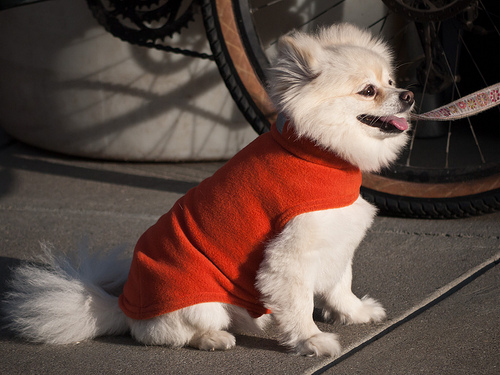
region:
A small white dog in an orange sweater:
[6, 23, 416, 360]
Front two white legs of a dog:
[256, 205, 384, 357]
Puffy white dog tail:
[6, 240, 132, 345]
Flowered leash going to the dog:
[398, 83, 498, 123]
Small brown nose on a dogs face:
[396, 85, 415, 106]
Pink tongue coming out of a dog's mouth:
[378, 113, 408, 132]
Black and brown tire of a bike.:
[199, 1, 497, 217]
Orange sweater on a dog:
[118, 117, 361, 320]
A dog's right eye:
[358, 81, 375, 98]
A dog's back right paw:
[191, 328, 237, 350]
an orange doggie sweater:
[118, 122, 362, 319]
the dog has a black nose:
[398, 88, 414, 108]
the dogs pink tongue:
[388, 114, 409, 131]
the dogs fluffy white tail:
[1, 238, 120, 348]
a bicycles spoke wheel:
[414, 0, 498, 219]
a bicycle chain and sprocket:
[73, 0, 215, 62]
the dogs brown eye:
[356, 82, 377, 98]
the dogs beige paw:
[188, 327, 236, 354]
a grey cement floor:
[386, 211, 498, 373]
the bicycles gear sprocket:
[86, 0, 207, 44]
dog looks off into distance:
[2, 23, 419, 363]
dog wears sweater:
[0, 21, 418, 361]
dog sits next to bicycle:
[5, 4, 497, 356]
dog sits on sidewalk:
[2, 24, 497, 371]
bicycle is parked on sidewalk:
[1, 0, 498, 372]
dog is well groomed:
[4, 21, 428, 358]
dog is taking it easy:
[3, 25, 414, 358]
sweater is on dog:
[2, 21, 417, 361]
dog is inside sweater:
[7, 20, 422, 360]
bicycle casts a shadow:
[0, 0, 491, 222]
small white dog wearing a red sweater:
[41, 20, 422, 350]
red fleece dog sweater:
[127, 138, 357, 315]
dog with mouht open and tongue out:
[356, 78, 416, 138]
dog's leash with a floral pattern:
[401, 78, 498, 135]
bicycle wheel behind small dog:
[233, 7, 495, 212]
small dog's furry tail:
[19, 230, 137, 354]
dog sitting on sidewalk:
[25, 48, 418, 360]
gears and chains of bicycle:
[94, 0, 213, 73]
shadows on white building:
[43, 24, 246, 177]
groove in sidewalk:
[304, 250, 498, 372]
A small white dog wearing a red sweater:
[233, 24, 414, 350]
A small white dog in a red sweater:
[263, 11, 487, 342]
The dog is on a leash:
[374, 70, 489, 140]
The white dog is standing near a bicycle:
[201, 2, 401, 191]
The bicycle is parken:
[397, 138, 496, 247]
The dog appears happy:
[321, 70, 418, 158]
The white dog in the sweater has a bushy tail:
[16, 272, 214, 352]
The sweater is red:
[170, 212, 242, 282]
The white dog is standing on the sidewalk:
[243, 204, 425, 355]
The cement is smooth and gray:
[398, 255, 476, 362]